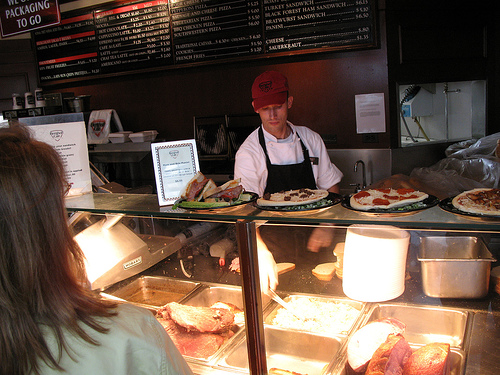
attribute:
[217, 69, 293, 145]
cap — red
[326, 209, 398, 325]
plates — white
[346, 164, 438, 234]
pizza — uncooked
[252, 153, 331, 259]
apron — black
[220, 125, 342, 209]
shirt — white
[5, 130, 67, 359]
hair — brown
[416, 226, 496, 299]
container — rectangle, silver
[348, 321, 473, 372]
pieces — ham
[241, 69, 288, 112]
cap — employee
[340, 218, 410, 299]
plates — white, styrofoam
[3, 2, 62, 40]
sign — to go orders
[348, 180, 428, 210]
pizza — pepperoni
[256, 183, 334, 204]
pizza — sausage, cheese, gourmet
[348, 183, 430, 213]
pizza — gourmet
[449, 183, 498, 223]
pizza — gourmet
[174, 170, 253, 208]
dish — gourmet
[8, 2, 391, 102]
menu — red, black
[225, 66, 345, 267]
line cook — preparing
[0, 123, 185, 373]
lady — waiting, long haired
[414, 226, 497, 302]
bin — silver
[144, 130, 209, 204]
sign — daily special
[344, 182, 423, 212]
pizza — pepperoni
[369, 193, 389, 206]
slices — large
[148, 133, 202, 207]
paper — white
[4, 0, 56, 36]
sign — Packagin to go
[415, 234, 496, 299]
tub — square, silver, metal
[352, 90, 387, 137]
paper — white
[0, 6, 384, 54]
menu — large, black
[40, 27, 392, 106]
wall — back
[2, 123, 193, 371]
woman — shopping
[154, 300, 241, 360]
conatiner — beef, roast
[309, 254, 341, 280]
bread — piece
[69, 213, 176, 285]
slicer — silver, metal, meat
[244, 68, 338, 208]
person — white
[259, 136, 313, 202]
apron — black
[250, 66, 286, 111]
hat — red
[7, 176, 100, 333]
hair — long, brown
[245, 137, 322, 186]
apron — black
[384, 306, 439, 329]
pan — silver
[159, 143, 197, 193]
writing — black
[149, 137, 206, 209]
paper — white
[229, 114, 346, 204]
shirt — white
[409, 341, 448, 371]
food — piece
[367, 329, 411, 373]
food — piece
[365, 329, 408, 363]
food — piece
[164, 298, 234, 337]
food — piece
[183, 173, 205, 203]
food — piece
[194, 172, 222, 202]
food — piece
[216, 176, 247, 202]
food — piece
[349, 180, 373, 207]
food — piece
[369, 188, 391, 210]
food — piece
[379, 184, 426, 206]
food — piece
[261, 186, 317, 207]
food — piece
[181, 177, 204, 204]
food — piece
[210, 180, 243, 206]
food — piece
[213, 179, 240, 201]
food — piece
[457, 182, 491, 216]
food — piece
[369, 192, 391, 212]
food — piece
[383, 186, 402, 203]
food — piece